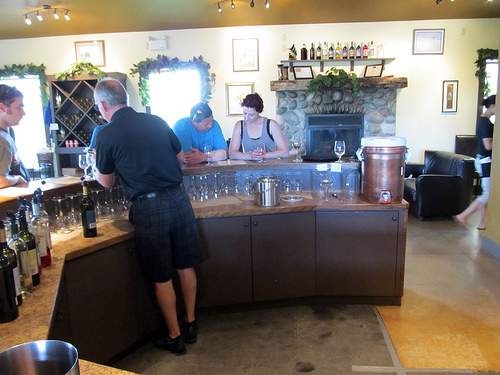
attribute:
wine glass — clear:
[336, 140, 346, 159]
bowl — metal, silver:
[7, 340, 73, 374]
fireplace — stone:
[278, 79, 410, 159]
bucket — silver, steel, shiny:
[253, 178, 281, 211]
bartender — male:
[92, 87, 203, 348]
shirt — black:
[100, 123, 178, 185]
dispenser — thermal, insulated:
[358, 138, 410, 204]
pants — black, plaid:
[132, 199, 200, 272]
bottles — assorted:
[9, 221, 45, 299]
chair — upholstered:
[410, 149, 473, 213]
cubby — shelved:
[42, 83, 113, 151]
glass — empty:
[55, 196, 75, 238]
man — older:
[96, 79, 208, 358]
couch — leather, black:
[407, 145, 472, 211]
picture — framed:
[435, 80, 463, 115]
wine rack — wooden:
[47, 79, 119, 146]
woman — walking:
[478, 89, 497, 222]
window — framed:
[480, 48, 500, 130]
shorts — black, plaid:
[134, 196, 209, 279]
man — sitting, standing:
[166, 105, 227, 162]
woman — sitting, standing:
[232, 94, 290, 161]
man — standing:
[0, 81, 32, 187]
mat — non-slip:
[145, 301, 399, 370]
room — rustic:
[4, 13, 496, 369]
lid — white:
[363, 134, 404, 150]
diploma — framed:
[410, 25, 444, 57]